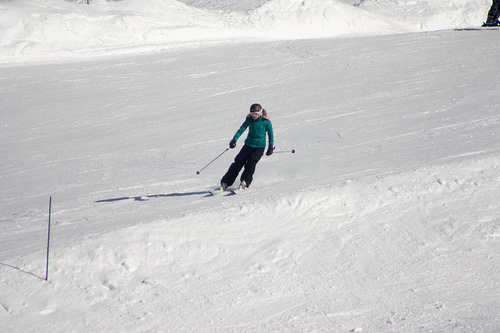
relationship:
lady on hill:
[220, 103, 276, 190] [65, 102, 172, 243]